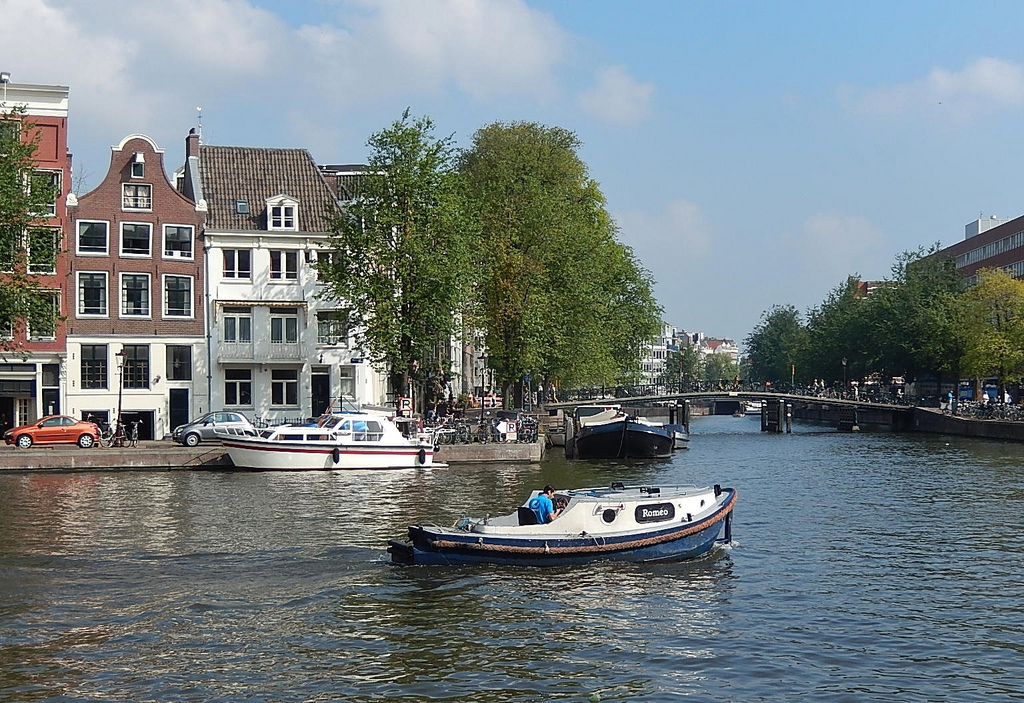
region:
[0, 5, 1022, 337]
Blue sky with some white clouds.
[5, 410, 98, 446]
A small orange car.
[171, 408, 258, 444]
Small silver car.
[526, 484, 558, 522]
Man in a blue shirt on a boat.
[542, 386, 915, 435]
A grey slightly curved up bridge.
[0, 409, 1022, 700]
A dark rippled body of water.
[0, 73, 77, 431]
Tallest red brick building with white trim top.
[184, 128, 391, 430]
White four story house with pitched brown roof.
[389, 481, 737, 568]
A white and blue boat with brown haired man in a blue shirt.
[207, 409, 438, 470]
A white boat parked along the concrete wall.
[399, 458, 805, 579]
white and blue boat in canal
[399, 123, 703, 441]
trees growing alongside canal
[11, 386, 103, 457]
red car alongside canal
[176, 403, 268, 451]
silver car alongside canal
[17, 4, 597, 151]
puffy white clouds in sky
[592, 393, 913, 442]
bridge crossing small canal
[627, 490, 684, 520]
small window on small boat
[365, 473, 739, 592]
white boat in canal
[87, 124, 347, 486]
white and brown house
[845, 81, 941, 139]
white clouds in blue sky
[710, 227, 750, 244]
white clouds in blue sky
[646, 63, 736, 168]
white clouds in blue sky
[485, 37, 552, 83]
white clouds in blue sky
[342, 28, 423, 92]
white clouds in blue sky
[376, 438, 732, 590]
boat in canal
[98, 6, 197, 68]
white clouds in the blue sky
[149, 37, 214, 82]
white clouds in the blue sky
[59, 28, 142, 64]
white clouds in the blue sky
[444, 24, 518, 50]
white clouds in the blue sky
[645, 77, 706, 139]
white clouds in the blue sky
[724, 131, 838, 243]
white clouds in the blue sky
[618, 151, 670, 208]
white clouds in the blue sky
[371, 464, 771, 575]
boat in water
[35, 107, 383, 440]
brown and white houses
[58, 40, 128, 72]
white clouds in blue sky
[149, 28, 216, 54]
white clouds in blue sky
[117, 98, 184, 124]
white clouds in blue sky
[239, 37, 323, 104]
white clouds in blue sky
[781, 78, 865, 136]
white clouds in blue sky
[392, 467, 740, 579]
boat is white and blue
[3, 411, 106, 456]
orange car parked on road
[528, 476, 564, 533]
man on boat sitting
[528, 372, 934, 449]
bridge overpass over river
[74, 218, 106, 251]
glass window on the building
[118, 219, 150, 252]
glass window on the building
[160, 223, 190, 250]
glass window on the building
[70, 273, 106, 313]
glass window on the building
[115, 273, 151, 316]
glass window on the building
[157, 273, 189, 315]
glass window on the building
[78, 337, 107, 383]
glass window on the building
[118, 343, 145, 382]
glass window on the building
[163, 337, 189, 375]
glass window on the building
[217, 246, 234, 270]
glass window on the building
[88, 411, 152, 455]
bicycle by the lamp pole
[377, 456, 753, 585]
boat driving through the water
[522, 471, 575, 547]
man driving the boat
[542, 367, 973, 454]
bridge over the water way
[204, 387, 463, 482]
boat parked along the street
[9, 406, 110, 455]
red car parked in front of bicycles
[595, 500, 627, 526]
round window on side of boat